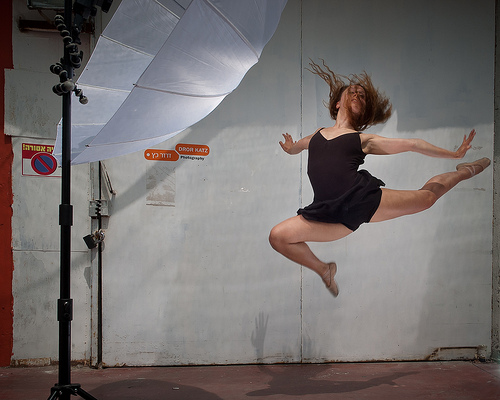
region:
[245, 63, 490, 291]
this is a lady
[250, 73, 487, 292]
the lady is on air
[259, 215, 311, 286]
the knee is bent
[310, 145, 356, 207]
the dress is black in color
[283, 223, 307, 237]
the lady is light skinned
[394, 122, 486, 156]
the hand is behind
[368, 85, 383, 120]
the hair is wavy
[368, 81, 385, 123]
the hair is long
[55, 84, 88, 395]
this is a pole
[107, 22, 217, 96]
this is an umbrella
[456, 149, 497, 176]
tan satin ballet shoe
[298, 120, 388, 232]
black stretchy exercise dress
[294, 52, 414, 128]
woman with long brown hair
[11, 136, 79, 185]
red yellow and blue warning sign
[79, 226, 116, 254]
black and silver padlock on pole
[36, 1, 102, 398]
black and gray photography light pole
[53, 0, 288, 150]
white photography light umbrella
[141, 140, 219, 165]
orange and white Hebrew signs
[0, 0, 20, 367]
orange and white paint stripe on wall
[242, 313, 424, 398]
woman's shadow on floor and wall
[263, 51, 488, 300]
woman with black outfit leaping in the air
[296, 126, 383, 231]
black outfit of a leaping woman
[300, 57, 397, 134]
flying long brown hair of a leaping woman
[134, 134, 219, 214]
red and black signs on a white wall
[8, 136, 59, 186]
red and gray sign on a white wall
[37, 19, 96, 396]
black metal piping in front of white wall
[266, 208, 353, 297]
bent right leg of a leaping woman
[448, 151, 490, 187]
ankle and pointed foot of leaping woman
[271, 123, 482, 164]
outstretched arms of a leaping woman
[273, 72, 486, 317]
person in the air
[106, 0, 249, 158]
light on the woman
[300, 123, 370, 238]
girl wearing a black dress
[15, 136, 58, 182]
sign of red and blue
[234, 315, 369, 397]
reflection on the ground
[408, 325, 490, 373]
marking on the curtain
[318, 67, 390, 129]
hair in front of face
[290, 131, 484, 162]
arms opened on woman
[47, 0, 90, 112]
electrical wires for lights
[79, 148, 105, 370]
poles for taking photos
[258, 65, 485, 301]
this is a lady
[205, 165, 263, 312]
this is the wall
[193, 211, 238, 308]
the wall is light skinned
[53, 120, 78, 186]
the pole is black in color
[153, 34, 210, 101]
the umbrella is white in color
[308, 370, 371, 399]
the floor is brown in color